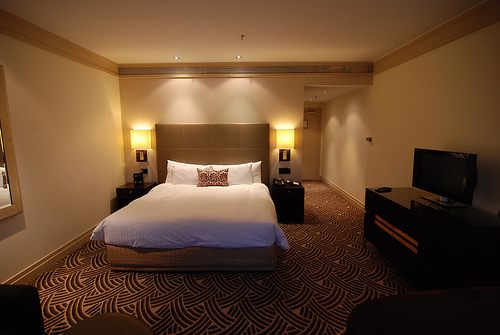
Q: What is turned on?
A: Lights.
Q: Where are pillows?
A: On the bed.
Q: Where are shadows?
A: On the wall.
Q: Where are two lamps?
A: On the wall.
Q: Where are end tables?
A: On both sides of the bed.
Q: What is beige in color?
A: The walls.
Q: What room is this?
A: Bedroom.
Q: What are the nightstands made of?
A: Wood.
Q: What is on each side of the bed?
A: Nightstands.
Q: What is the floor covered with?
A: Carpet.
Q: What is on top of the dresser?
A: TV.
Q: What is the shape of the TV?
A: Rectangle.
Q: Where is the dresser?
A: On the right against the wall.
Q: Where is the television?
A: On the stand at the side of the room.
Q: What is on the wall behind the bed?
A: Lights are on the wall.